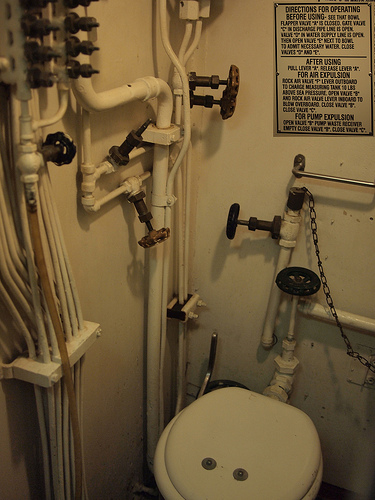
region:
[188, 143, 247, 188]
this is the wall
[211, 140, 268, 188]
the wall is white in color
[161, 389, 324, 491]
this is a toilet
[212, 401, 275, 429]
this is the toilet lid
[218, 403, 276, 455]
the lid is white in color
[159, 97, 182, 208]
these are several pipes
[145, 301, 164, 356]
the pipes are white in color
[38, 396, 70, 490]
these are some wires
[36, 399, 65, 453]
the wires are white in color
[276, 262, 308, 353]
this is a tap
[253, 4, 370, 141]
A white sign with black letters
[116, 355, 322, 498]
A white toilet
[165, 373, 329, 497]
The lid of a white toilet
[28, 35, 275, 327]
Plumbing in a bathroom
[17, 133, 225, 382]
white pipes on a wall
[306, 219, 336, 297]
links of a black chain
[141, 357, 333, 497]
A toilet with the lid down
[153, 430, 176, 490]
The seat of a toilet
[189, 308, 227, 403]
A solver handle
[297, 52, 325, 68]
The word "AFTER"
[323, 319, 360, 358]
part of a chain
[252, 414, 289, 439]
part of a lid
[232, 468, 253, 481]
part of a bolt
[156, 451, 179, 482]
edge of a lid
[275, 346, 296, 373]
part of a bolt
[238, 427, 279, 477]
part of a toilet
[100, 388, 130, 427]
part of a wall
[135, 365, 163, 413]
part of a pipe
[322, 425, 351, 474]
part of a wall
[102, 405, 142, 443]
part of a wall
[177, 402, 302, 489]
this is a toilet sink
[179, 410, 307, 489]
the lid is closed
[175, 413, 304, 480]
the lid is white in color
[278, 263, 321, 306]
this is a tap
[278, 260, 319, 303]
the tap is black in color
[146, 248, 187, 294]
pipes are on the wall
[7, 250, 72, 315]
the pipes are many in number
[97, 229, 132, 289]
the wall is white in color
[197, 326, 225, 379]
this is a metal beside the sink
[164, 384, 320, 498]
the toilet is white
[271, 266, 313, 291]
there is a black turn off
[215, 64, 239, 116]
there are two knobs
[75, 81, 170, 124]
the pipe is white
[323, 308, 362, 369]
there is a chain to flush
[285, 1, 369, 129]
there is a sign hanging over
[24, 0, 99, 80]
there are many knobs attached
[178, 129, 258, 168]
the wall is white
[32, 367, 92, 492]
there are many pipe lines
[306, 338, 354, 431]
the wall is dirty